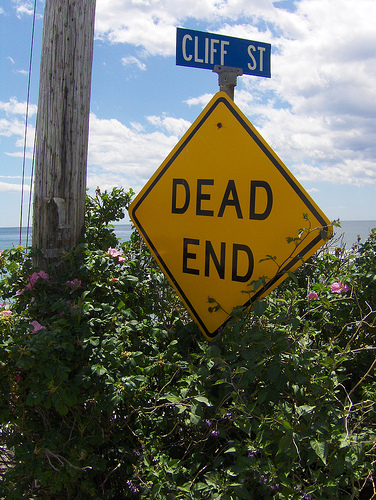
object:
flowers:
[63, 277, 84, 289]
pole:
[17, 2, 39, 247]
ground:
[325, 128, 340, 144]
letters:
[169, 175, 275, 220]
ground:
[331, 82, 354, 110]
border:
[128, 90, 333, 338]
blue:
[0, 2, 373, 229]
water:
[0, 220, 373, 249]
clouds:
[0, 0, 376, 196]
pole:
[31, 0, 94, 270]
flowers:
[307, 292, 319, 301]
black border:
[223, 102, 327, 228]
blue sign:
[175, 27, 271, 76]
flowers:
[31, 320, 46, 335]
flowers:
[107, 246, 122, 257]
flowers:
[331, 281, 352, 293]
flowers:
[37, 270, 49, 280]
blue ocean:
[0, 218, 373, 258]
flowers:
[303, 491, 310, 500]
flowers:
[275, 481, 280, 488]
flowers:
[210, 426, 220, 439]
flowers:
[248, 446, 256, 459]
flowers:
[126, 479, 140, 492]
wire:
[24, 111, 38, 254]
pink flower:
[118, 256, 128, 263]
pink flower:
[71, 279, 82, 292]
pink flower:
[25, 318, 42, 335]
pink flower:
[24, 272, 40, 290]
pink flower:
[0, 308, 12, 316]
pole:
[212, 62, 241, 104]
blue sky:
[0, 1, 375, 226]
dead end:
[168, 175, 273, 284]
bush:
[0, 182, 376, 497]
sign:
[127, 90, 333, 343]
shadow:
[0, 258, 138, 500]